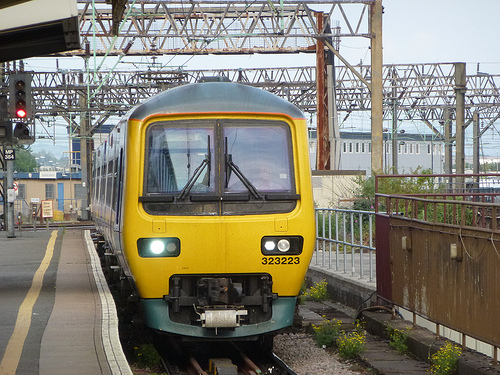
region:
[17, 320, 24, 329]
the line is yellow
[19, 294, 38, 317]
the line is yellow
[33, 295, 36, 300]
the line is yellow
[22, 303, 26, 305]
the line is yellow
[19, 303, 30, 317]
the line is yellow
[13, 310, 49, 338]
the line is yellow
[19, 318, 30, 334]
the line is yellow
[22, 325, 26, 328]
the line is yellow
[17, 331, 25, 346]
the line is yellow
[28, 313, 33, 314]
the line is yellow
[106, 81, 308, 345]
The train is yellow.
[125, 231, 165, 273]
The light is on.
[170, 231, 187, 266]
The light is off.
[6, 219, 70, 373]
The painted line is yellow.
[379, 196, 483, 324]
The fence is brown.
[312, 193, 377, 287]
The fence is metal.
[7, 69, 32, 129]
The traffic light is black.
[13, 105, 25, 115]
The red light is on.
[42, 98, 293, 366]
THe train is at the train station.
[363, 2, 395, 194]
The poles are wood.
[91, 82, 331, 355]
A train riding down a track.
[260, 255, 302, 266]
The number 323223 on the front of the train.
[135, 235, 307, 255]
The front headlights of the train.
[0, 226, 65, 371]
A yellow line painted on the concrete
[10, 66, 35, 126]
A traffic light on the red light.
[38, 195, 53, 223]
A sign with a red frame and yellow center.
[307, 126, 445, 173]
A grey building with a black roof.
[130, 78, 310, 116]
The green top of the front of the train.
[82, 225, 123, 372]
A white double line at the platforms edge.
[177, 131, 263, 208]
The train's windshield wipers.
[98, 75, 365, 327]
yellow train on the tracks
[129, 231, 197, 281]
light on the train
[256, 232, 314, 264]
lights on the train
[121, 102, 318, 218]
window on the train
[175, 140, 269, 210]
windshield wipers on the train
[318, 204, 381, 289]
fence next to the train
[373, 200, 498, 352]
fence next to the train tracks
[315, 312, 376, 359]
weeds growing near the train tracks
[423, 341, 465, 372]
weeds growing near the train tracks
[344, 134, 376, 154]
windows on buildings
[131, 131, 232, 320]
the train is yellow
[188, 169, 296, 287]
the train is yellow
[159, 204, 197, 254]
the train is yellow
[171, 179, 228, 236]
the train is yellow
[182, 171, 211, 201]
the train is yellow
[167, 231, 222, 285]
the train is yellow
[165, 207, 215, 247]
the train is yellow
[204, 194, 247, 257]
the train is yellow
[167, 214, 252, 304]
the train is yellow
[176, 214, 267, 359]
the train is yellow